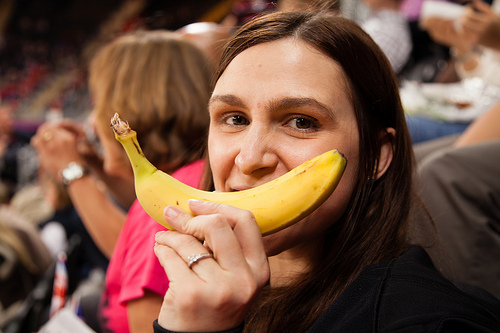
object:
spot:
[176, 200, 179, 206]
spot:
[312, 186, 317, 190]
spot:
[295, 169, 307, 177]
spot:
[130, 137, 141, 154]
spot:
[117, 137, 121, 140]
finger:
[154, 230, 220, 279]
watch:
[59, 160, 92, 188]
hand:
[151, 196, 272, 331]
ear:
[367, 121, 397, 182]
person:
[30, 98, 132, 303]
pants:
[402, 134, 500, 302]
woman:
[149, 9, 476, 332]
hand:
[30, 123, 89, 179]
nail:
[164, 205, 184, 220]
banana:
[109, 112, 347, 242]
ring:
[186, 252, 213, 268]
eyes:
[277, 113, 327, 133]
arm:
[56, 160, 128, 259]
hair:
[214, 10, 417, 332]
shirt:
[102, 153, 205, 332]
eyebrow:
[265, 95, 341, 128]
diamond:
[188, 255, 196, 260]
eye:
[215, 109, 249, 132]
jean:
[404, 106, 467, 144]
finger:
[187, 197, 265, 261]